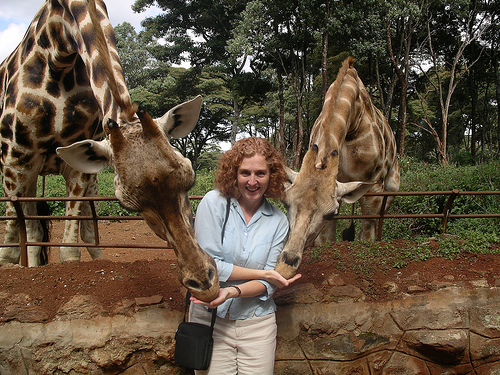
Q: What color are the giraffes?
A: Brown and white.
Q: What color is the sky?
A: Blue.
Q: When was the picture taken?
A: Daytime.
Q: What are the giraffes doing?
A: Eating.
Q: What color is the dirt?
A: Brown.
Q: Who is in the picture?
A: The woman.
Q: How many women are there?
A: One.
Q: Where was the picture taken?
A: At the giraffe exhibit at the zoo.